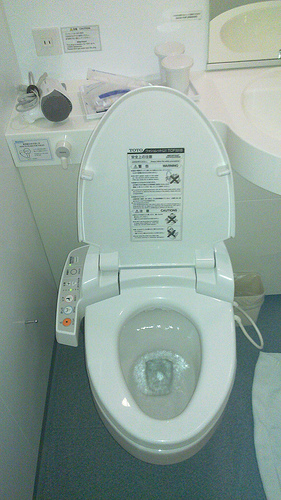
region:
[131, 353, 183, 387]
water in the toilet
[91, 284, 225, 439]
a white toilet seat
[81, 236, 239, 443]
a toilet on the ground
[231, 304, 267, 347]
a cord on the toilet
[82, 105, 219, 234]
the toilet seat lid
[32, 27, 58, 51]
an electrical socket in the wall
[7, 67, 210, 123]
the back of the toilet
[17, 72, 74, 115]
a hair dryer on the shelf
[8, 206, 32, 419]
a white wall next to the toilet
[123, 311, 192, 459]
a white hole in toilet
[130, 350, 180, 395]
water inside the whole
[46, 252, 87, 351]
a side display on toilet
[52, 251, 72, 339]
buttons on the side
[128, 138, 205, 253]
a display of usage chart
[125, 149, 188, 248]
a usage chart attached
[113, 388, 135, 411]
light falling on toilet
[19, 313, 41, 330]
a hanger to the wall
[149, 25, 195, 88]
two cups on the table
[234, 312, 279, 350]
a small wire to toilet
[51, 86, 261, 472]
white toilet with open lid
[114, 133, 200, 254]
toilet lid with instructions printed on it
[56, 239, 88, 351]
control panel for toilet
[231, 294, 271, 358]
tubing sticks out from side of toilet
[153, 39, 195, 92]
specimen cups on shelf behind toilet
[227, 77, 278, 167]
small sink next to toilet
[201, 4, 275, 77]
mirror above sink next to toilet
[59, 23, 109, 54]
small sign on wall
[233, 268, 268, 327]
small brown trash can next to toilet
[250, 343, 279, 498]
towel on floor in front of sink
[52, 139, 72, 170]
toilet handle on tank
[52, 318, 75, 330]
button attached to toilet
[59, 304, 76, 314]
button attached to toilet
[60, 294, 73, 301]
button attached to toilet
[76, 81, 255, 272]
toilet lid attached to toilet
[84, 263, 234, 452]
toilet seat attached to toilet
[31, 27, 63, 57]
outlet on the wall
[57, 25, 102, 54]
sign on the wall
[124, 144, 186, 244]
sign on the toilet lid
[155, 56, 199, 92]
container on the toilet tank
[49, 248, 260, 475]
toilet in the airplane